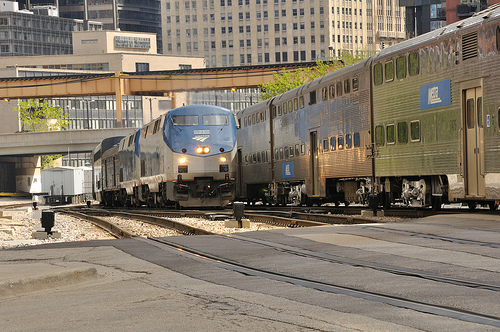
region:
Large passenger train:
[92, 100, 247, 215]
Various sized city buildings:
[0, 0, 249, 107]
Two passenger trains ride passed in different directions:
[93, 29, 497, 216]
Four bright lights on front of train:
[158, 131, 248, 176]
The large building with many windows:
[163, 0, 402, 62]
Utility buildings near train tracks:
[35, 160, 102, 201]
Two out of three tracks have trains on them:
[67, 186, 468, 237]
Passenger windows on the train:
[236, 80, 368, 170]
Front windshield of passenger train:
[165, 109, 233, 131]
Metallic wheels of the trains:
[90, 173, 490, 213]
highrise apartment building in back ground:
[161, 0, 405, 60]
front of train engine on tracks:
[166, 105, 242, 191]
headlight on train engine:
[177, 155, 186, 163]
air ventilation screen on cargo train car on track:
[351, 130, 362, 147]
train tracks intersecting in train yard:
[58, 202, 495, 330]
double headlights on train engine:
[193, 145, 211, 153]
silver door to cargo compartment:
[461, 93, 484, 199]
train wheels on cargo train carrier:
[374, 176, 446, 213]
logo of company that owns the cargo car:
[418, 84, 455, 107]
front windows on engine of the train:
[171, 111, 233, 130]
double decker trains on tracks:
[66, 12, 498, 235]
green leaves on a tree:
[8, 98, 78, 131]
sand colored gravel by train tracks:
[59, 210, 86, 240]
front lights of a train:
[194, 145, 213, 157]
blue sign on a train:
[417, 78, 457, 113]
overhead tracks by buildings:
[2, 55, 356, 103]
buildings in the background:
[4, 0, 411, 51]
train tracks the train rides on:
[150, 245, 495, 323]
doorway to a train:
[454, 78, 499, 209]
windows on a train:
[371, 110, 428, 149]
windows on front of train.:
[170, 111, 225, 122]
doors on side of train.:
[464, 88, 481, 195]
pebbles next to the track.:
[70, 218, 87, 232]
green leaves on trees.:
[264, 72, 314, 86]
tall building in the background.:
[222, 12, 295, 34]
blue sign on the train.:
[422, 79, 447, 102]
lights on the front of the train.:
[195, 145, 212, 155]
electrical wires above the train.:
[30, 72, 108, 100]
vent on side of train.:
[462, 34, 477, 57]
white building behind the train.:
[43, 170, 78, 190]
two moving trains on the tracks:
[91, 3, 498, 210]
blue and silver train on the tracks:
[91, 105, 240, 212]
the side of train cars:
[242, 6, 498, 209]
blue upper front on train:
[162, 102, 237, 157]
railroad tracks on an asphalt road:
[88, 210, 498, 328]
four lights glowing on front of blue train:
[176, 145, 223, 160]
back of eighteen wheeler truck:
[40, 161, 86, 201]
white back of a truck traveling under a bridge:
[40, 165, 90, 200]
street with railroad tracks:
[117, 237, 499, 330]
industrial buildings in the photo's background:
[1, 1, 404, 41]